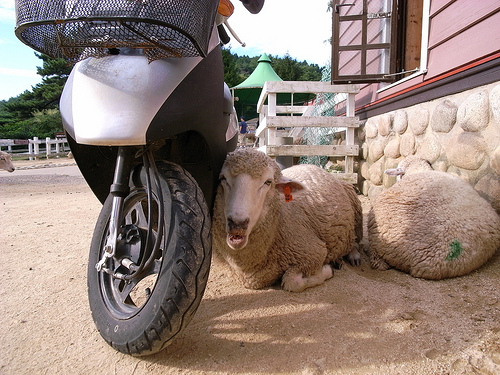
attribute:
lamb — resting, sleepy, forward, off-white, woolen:
[222, 141, 356, 286]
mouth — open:
[225, 232, 248, 245]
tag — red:
[268, 192, 307, 207]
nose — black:
[232, 211, 250, 239]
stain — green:
[439, 237, 463, 258]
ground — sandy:
[218, 299, 470, 357]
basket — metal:
[15, 2, 233, 65]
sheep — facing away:
[354, 159, 496, 274]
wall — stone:
[322, 72, 495, 207]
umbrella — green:
[211, 40, 288, 100]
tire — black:
[46, 151, 197, 349]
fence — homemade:
[250, 79, 365, 198]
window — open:
[313, 1, 430, 103]